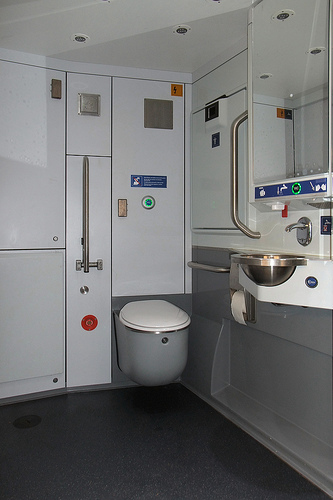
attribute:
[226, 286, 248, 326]
toilet pape — Roll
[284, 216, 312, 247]
faucet — dispensing water  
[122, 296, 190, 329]
lid — closed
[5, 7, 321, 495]
building — side 